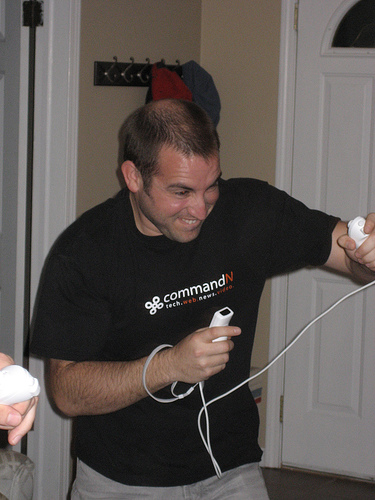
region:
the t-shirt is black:
[39, 181, 289, 464]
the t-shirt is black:
[37, 173, 297, 476]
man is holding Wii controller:
[130, 289, 247, 447]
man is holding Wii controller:
[124, 278, 245, 427]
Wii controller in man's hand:
[208, 304, 232, 340]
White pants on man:
[68, 459, 271, 498]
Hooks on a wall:
[96, 54, 194, 90]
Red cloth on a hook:
[147, 62, 187, 96]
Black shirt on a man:
[25, 176, 337, 485]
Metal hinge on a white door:
[279, 393, 285, 422]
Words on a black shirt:
[146, 270, 233, 316]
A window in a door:
[327, 4, 373, 52]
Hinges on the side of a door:
[21, 1, 42, 26]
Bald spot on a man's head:
[151, 99, 185, 123]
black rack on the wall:
[86, 45, 209, 96]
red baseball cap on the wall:
[145, 55, 189, 106]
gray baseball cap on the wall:
[184, 65, 224, 127]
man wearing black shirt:
[39, 70, 325, 479]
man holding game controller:
[27, 76, 324, 498]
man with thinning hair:
[32, 82, 314, 481]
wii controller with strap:
[157, 305, 255, 460]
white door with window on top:
[281, 13, 365, 484]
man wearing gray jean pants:
[32, 71, 301, 489]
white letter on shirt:
[160, 284, 175, 306]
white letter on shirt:
[163, 279, 181, 310]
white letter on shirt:
[175, 275, 192, 311]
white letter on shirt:
[182, 280, 201, 300]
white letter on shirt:
[201, 275, 210, 298]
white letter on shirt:
[207, 267, 222, 302]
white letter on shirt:
[159, 301, 169, 311]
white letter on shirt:
[170, 299, 176, 310]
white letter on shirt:
[172, 298, 182, 315]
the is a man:
[10, 52, 373, 498]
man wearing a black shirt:
[31, 146, 342, 493]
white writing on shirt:
[141, 249, 242, 329]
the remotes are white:
[142, 176, 372, 497]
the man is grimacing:
[117, 142, 232, 245]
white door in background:
[260, 5, 373, 474]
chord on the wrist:
[123, 314, 244, 415]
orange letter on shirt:
[217, 256, 238, 289]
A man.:
[26, 97, 368, 498]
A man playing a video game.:
[28, 96, 374, 499]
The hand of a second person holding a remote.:
[1, 349, 44, 484]